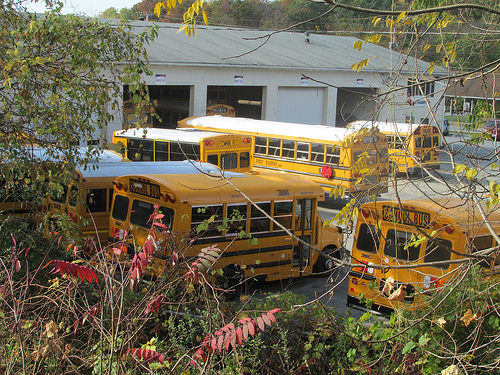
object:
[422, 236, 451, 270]
window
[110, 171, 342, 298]
bus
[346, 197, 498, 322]
bus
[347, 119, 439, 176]
bus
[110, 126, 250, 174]
bus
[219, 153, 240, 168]
window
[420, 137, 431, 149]
window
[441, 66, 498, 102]
roof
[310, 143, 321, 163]
window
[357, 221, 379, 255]
bus window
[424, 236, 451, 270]
bus window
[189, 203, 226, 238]
bus window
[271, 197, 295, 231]
bus window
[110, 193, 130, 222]
bus window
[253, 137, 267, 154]
window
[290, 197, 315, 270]
door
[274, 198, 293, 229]
window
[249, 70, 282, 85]
wall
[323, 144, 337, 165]
window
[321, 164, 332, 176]
sign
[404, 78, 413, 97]
window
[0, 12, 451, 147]
building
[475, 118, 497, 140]
van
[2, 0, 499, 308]
school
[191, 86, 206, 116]
wall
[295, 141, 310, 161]
window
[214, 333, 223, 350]
leaf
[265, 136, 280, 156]
window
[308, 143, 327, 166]
window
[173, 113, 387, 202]
bus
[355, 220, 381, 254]
window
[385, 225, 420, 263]
window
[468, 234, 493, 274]
window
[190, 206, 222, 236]
window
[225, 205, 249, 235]
window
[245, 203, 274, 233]
window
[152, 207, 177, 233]
window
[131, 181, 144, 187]
stripe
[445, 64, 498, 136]
house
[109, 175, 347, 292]
bus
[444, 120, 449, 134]
car